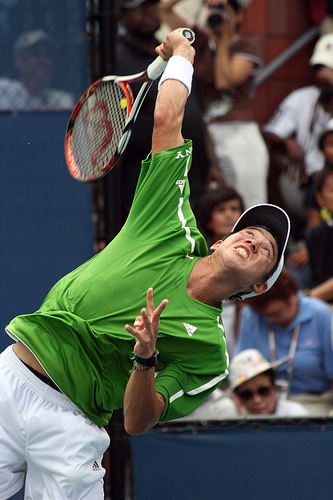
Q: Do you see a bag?
A: No, there are no bags.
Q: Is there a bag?
A: No, there are no bags.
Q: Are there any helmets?
A: No, there are no helmets.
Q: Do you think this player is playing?
A: Yes, the player is playing.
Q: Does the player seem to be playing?
A: Yes, the player is playing.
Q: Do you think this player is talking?
A: No, the player is playing.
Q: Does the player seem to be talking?
A: No, the player is playing.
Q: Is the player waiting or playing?
A: The player is playing.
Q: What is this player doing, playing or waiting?
A: The player is playing.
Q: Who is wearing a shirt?
A: The player is wearing a shirt.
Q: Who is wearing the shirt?
A: The player is wearing a shirt.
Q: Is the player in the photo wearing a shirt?
A: Yes, the player is wearing a shirt.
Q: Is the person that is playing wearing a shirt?
A: Yes, the player is wearing a shirt.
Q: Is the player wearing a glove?
A: No, the player is wearing a shirt.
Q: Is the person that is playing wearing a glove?
A: No, the player is wearing a shirt.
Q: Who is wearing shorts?
A: The player is wearing shorts.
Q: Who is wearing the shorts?
A: The player is wearing shorts.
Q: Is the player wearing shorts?
A: Yes, the player is wearing shorts.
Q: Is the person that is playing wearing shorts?
A: Yes, the player is wearing shorts.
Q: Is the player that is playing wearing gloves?
A: No, the player is wearing shorts.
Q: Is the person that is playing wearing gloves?
A: No, the player is wearing shorts.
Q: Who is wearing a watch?
A: The player is wearing a watch.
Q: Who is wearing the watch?
A: The player is wearing a watch.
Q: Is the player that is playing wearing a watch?
A: Yes, the player is wearing a watch.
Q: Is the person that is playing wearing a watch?
A: Yes, the player is wearing a watch.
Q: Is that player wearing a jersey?
A: No, the player is wearing a watch.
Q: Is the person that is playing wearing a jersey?
A: No, the player is wearing a watch.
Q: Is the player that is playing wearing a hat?
A: Yes, the player is wearing a hat.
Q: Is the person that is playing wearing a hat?
A: Yes, the player is wearing a hat.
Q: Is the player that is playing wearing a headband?
A: No, the player is wearing a hat.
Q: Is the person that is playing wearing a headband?
A: No, the player is wearing a hat.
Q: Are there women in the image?
A: Yes, there is a woman.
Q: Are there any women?
A: Yes, there is a woman.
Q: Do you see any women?
A: Yes, there is a woman.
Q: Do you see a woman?
A: Yes, there is a woman.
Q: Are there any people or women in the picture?
A: Yes, there is a woman.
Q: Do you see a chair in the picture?
A: No, there are no chairs.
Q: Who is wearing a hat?
A: The woman is wearing a hat.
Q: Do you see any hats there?
A: Yes, there is a hat.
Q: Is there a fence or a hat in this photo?
A: Yes, there is a hat.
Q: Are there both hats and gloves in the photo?
A: No, there is a hat but no gloves.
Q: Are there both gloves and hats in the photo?
A: No, there is a hat but no gloves.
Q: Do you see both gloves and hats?
A: No, there is a hat but no gloves.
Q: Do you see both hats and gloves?
A: No, there is a hat but no gloves.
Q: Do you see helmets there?
A: No, there are no helmets.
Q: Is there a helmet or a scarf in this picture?
A: No, there are no helmets or scarves.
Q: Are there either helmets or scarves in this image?
A: No, there are no helmets or scarves.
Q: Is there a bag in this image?
A: No, there are no bags.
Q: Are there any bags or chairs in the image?
A: No, there are no bags or chairs.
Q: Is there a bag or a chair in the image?
A: No, there are no bags or chairs.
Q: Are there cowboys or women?
A: Yes, there is a woman.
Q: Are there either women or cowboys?
A: Yes, there is a woman.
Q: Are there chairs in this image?
A: No, there are no chairs.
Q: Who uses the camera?
A: The woman uses the camera.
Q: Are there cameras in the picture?
A: Yes, there is a camera.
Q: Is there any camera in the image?
A: Yes, there is a camera.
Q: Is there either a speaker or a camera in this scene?
A: Yes, there is a camera.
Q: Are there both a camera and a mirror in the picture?
A: No, there is a camera but no mirrors.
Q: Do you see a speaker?
A: No, there are no speakers.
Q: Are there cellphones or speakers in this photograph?
A: No, there are no speakers or cellphones.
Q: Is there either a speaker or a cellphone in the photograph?
A: No, there are no speakers or cell phones.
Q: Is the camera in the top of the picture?
A: Yes, the camera is in the top of the image.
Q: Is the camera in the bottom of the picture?
A: No, the camera is in the top of the image.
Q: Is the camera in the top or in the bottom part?
A: The camera is in the top of the image.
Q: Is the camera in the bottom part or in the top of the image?
A: The camera is in the top of the image.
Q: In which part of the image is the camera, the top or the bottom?
A: The camera is in the top of the image.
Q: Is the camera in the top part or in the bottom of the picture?
A: The camera is in the top of the image.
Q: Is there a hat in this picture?
A: Yes, there is a hat.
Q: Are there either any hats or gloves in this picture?
A: Yes, there is a hat.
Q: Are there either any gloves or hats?
A: Yes, there is a hat.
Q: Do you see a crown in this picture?
A: No, there are no crowns.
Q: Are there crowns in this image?
A: No, there are no crowns.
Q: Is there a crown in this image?
A: No, there are no crowns.